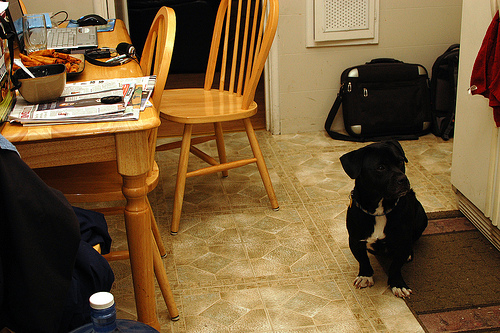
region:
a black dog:
[342, 142, 431, 297]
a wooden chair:
[163, 0, 285, 232]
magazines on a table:
[18, 77, 156, 123]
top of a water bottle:
[89, 292, 115, 311]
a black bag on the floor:
[323, 58, 438, 140]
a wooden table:
[2, 25, 167, 327]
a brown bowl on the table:
[13, 67, 66, 98]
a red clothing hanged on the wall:
[470, 10, 498, 117]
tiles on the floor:
[172, 195, 372, 327]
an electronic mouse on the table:
[76, 12, 110, 26]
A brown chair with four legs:
[150, 1, 281, 236]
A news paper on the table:
[8, 71, 157, 127]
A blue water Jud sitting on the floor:
[70, 291, 159, 331]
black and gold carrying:
[324, 56, 434, 141]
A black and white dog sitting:
[339, 139, 430, 300]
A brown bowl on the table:
[8, 55, 71, 106]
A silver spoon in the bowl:
[13, 56, 37, 78]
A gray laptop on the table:
[8, 0, 99, 53]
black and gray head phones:
[80, 40, 138, 69]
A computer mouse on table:
[72, 11, 109, 27]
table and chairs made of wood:
[20, 3, 291, 320]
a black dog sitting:
[331, 137, 441, 308]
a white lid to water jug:
[86, 288, 118, 310]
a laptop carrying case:
[318, 50, 437, 141]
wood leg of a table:
[110, 135, 170, 320]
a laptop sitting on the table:
[6, 2, 104, 57]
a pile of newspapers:
[18, 75, 161, 150]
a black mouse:
[62, 12, 117, 33]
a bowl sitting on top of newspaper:
[9, 46, 118, 134]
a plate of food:
[8, 42, 86, 76]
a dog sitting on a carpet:
[331, 132, 439, 298]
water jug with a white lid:
[83, 291, 144, 331]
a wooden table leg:
[116, 165, 159, 285]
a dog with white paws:
[347, 267, 420, 307]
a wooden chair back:
[211, 3, 283, 75]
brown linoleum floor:
[221, 222, 313, 298]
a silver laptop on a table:
[11, 0, 103, 52]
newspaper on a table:
[69, 70, 136, 124]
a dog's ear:
[335, 145, 372, 178]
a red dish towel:
[468, 9, 498, 119]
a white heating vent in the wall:
[305, 2, 383, 50]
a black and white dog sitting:
[332, 132, 436, 304]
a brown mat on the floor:
[351, 199, 498, 329]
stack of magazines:
[4, 75, 156, 133]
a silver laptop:
[2, 1, 100, 58]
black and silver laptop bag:
[321, 53, 438, 150]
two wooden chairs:
[131, 1, 285, 241]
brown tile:
[184, 209, 331, 331]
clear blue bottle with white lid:
[85, 286, 120, 331]